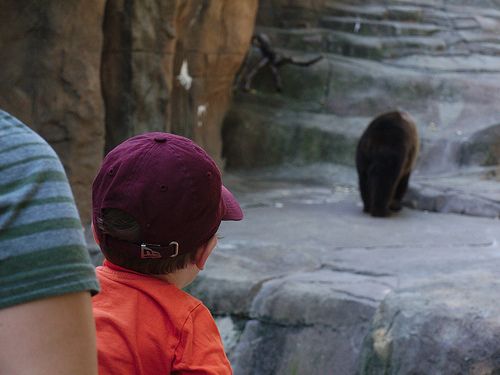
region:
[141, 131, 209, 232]
this is a cap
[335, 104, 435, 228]
this is a bear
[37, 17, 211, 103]
this is a tree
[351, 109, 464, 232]
the bear is black in colour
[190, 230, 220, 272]
this is the ear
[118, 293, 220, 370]
this is a shirt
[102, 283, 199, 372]
the shirt is orange in colour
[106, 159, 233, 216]
the cap is purple in colour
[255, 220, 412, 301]
this is a rock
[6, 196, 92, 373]
this is an arm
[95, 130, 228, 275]
hat on the boy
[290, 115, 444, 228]
brown bear at the zoo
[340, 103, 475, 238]
brown bear at the zoo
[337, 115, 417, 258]
brown bear at the zoo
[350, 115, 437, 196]
brown bear at the zoo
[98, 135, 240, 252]
the cap is red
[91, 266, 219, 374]
the shirt is orange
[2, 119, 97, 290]
the tshirt is green and blue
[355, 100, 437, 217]
the bear is grey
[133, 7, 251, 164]
the tree is dry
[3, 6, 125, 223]
the tree is dry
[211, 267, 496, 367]
the stones are white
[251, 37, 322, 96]
the branch has fallen down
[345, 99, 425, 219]
large brown bear on a rock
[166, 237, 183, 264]
silver buckle on a hat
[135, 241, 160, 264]
silver logo on a hat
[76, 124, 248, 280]
purple hat with silver logo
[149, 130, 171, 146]
button on the purple hat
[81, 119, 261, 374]
boy wearing a purple hat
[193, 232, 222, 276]
ear of a boy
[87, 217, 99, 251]
ear of a boy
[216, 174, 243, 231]
bill of a purple hat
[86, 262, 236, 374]
red shirt on a boy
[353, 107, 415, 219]
Large brown animal in zoo.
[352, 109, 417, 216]
Rear view of brown bear in zoo.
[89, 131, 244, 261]
Little boys purple baseball cap.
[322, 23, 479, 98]
Gray stone mountain like surroundings.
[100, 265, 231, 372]
Little boy's orange shirt.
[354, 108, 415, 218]
Brown furry coat of bear.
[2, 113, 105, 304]
Blue and green shirt sleeve.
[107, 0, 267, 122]
Rock wall structure enclosure in zoo.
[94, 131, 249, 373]
Little boy watching bear in zoo.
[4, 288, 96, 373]
Arm of person holding little boy.